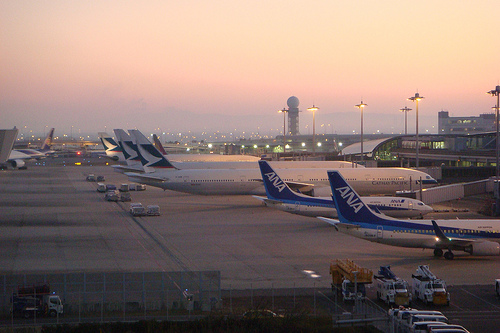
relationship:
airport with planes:
[19, 93, 486, 324] [116, 115, 478, 271]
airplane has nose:
[119, 128, 439, 210] [420, 172, 440, 190]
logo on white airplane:
[365, 177, 414, 195] [135, 163, 430, 197]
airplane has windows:
[119, 128, 439, 210] [290, 175, 335, 187]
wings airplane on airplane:
[431, 215, 474, 265] [325, 167, 496, 258]